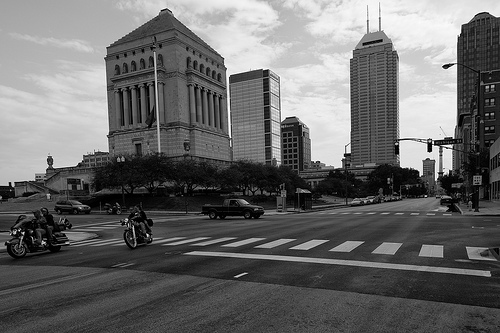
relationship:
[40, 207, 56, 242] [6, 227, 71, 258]
woman on motorcycle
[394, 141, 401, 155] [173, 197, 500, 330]
traffic light above street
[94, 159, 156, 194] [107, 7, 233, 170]
tree near building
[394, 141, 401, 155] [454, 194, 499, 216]
traffic light near sidewalk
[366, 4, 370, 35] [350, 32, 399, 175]
antenna on building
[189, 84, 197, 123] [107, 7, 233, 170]
column on building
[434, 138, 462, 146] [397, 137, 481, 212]
street sign on pole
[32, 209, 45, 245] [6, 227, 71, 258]
man on motorcycle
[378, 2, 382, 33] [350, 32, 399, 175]
antenna on building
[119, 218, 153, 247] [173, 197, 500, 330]
motorcycle on street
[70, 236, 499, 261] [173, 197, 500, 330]
crosswalk on street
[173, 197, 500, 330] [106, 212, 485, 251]
street has intersection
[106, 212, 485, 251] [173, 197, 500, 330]
intersection on street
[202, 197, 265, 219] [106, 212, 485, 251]
truck at intersection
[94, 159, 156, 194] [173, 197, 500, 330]
tree by street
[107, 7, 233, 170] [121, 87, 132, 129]
building has column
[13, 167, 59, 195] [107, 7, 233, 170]
steps lead to building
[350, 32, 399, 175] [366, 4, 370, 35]
building has antenna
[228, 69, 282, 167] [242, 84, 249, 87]
building has windows.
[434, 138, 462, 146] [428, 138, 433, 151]
street sign near traffic light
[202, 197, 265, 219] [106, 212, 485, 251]
truck crossing intersection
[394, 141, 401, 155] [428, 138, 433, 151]
traffic light near traffic light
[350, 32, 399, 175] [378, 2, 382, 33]
building has antenna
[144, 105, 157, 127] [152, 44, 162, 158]
flag on flag pole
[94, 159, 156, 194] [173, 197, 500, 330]
tree near street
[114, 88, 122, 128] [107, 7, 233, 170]
column on building